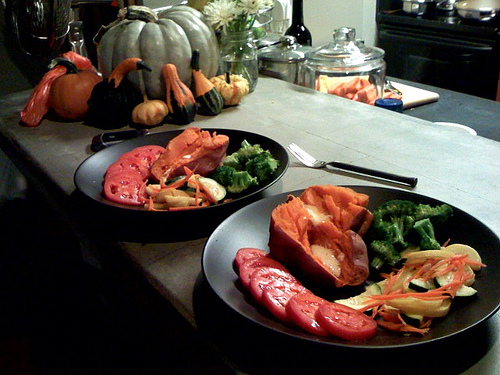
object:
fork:
[293, 146, 414, 186]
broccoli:
[368, 192, 449, 264]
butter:
[308, 244, 340, 277]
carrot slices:
[367, 252, 482, 325]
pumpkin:
[102, 4, 220, 79]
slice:
[316, 302, 378, 344]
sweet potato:
[268, 184, 371, 286]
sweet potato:
[150, 125, 227, 175]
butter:
[180, 153, 191, 159]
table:
[218, 79, 495, 217]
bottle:
[287, 0, 312, 37]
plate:
[209, 179, 494, 347]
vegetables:
[376, 248, 474, 309]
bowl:
[214, 188, 486, 352]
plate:
[70, 125, 290, 222]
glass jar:
[308, 31, 380, 94]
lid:
[291, 26, 388, 73]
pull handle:
[398, 20, 468, 58]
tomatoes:
[321, 300, 378, 340]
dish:
[212, 190, 490, 360]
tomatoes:
[102, 173, 143, 206]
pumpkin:
[53, 69, 100, 111]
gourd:
[185, 52, 222, 119]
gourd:
[158, 59, 196, 121]